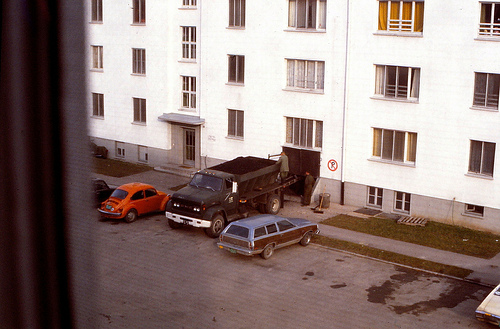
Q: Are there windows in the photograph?
A: Yes, there is a window.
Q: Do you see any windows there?
A: Yes, there is a window.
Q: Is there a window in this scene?
A: Yes, there is a window.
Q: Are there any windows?
A: Yes, there is a window.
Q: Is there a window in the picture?
A: Yes, there is a window.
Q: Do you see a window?
A: Yes, there is a window.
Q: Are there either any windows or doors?
A: Yes, there is a window.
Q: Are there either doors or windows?
A: Yes, there is a window.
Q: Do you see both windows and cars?
A: Yes, there are both a window and a car.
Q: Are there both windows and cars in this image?
A: Yes, there are both a window and a car.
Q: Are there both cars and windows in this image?
A: Yes, there are both a window and a car.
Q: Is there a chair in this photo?
A: No, there are no chairs.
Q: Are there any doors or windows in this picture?
A: Yes, there is a window.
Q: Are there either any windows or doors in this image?
A: Yes, there is a window.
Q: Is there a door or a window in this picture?
A: Yes, there is a window.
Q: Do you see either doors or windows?
A: Yes, there is a window.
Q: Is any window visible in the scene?
A: Yes, there is a window.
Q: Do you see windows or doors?
A: Yes, there is a window.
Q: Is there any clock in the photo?
A: No, there are no clocks.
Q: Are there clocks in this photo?
A: No, there are no clocks.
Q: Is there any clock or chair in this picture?
A: No, there are no clocks or chairs.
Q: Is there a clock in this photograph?
A: No, there are no clocks.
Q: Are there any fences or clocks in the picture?
A: No, there are no clocks or fences.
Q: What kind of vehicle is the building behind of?
A: The building is behind the car.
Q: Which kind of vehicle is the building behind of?
A: The building is behind the car.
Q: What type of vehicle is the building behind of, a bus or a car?
A: The building is behind a car.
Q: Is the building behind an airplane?
A: No, the building is behind the car.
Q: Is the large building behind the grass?
A: Yes, the building is behind the grass.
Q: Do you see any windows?
A: Yes, there is a window.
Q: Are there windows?
A: Yes, there is a window.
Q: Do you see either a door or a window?
A: Yes, there is a window.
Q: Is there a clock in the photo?
A: No, there are no clocks.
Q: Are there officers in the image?
A: No, there are no officers.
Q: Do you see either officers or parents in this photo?
A: No, there are no officers or parents.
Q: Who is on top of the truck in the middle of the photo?
A: The man is on top of the truck.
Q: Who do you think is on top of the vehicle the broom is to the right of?
A: The man is on top of the truck.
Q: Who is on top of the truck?
A: The man is on top of the truck.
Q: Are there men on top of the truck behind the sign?
A: Yes, there is a man on top of the truck.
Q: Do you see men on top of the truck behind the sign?
A: Yes, there is a man on top of the truck.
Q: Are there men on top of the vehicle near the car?
A: Yes, there is a man on top of the truck.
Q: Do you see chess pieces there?
A: No, there are no chess pieces.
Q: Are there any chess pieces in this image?
A: No, there are no chess pieces.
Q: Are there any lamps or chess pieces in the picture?
A: No, there are no chess pieces or lamps.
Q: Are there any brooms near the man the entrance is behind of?
A: Yes, there is a broom near the man.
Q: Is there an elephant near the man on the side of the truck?
A: No, there is a broom near the man.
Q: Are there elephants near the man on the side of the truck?
A: No, there is a broom near the man.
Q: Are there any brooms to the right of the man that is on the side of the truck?
A: Yes, there is a broom to the right of the man.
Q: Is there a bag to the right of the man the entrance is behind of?
A: No, there is a broom to the right of the man.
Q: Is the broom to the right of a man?
A: Yes, the broom is to the right of a man.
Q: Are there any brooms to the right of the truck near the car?
A: Yes, there is a broom to the right of the truck.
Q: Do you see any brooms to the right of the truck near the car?
A: Yes, there is a broom to the right of the truck.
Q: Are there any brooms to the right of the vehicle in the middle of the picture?
A: Yes, there is a broom to the right of the truck.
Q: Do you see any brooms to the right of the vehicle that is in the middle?
A: Yes, there is a broom to the right of the truck.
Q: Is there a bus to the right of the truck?
A: No, there is a broom to the right of the truck.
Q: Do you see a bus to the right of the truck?
A: No, there is a broom to the right of the truck.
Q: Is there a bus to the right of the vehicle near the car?
A: No, there is a broom to the right of the truck.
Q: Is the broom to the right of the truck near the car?
A: Yes, the broom is to the right of the truck.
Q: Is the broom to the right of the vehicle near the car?
A: Yes, the broom is to the right of the truck.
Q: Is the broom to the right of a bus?
A: No, the broom is to the right of the truck.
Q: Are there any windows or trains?
A: Yes, there is a window.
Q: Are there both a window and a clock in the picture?
A: No, there is a window but no clocks.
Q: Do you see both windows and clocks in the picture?
A: No, there is a window but no clocks.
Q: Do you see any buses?
A: No, there are no buses.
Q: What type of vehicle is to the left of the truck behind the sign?
A: The vehicle is a car.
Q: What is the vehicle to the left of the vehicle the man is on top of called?
A: The vehicle is a car.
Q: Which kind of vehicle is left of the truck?
A: The vehicle is a car.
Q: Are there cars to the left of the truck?
A: Yes, there is a car to the left of the truck.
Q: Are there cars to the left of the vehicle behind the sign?
A: Yes, there is a car to the left of the truck.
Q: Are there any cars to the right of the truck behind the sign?
A: No, the car is to the left of the truck.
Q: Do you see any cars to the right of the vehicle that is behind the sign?
A: No, the car is to the left of the truck.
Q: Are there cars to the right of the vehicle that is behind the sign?
A: No, the car is to the left of the truck.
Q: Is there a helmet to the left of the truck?
A: No, there is a car to the left of the truck.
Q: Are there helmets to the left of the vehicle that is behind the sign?
A: No, there is a car to the left of the truck.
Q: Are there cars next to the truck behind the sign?
A: Yes, there is a car next to the truck.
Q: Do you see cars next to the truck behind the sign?
A: Yes, there is a car next to the truck.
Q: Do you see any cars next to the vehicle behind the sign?
A: Yes, there is a car next to the truck.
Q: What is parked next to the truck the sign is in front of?
A: The car is parked next to the truck.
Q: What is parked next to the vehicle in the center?
A: The car is parked next to the truck.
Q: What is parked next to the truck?
A: The car is parked next to the truck.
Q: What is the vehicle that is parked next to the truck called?
A: The vehicle is a car.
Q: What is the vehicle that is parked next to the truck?
A: The vehicle is a car.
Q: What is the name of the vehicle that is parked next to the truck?
A: The vehicle is a car.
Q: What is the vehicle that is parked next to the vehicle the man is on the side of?
A: The vehicle is a car.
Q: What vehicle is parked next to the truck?
A: The vehicle is a car.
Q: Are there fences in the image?
A: No, there are no fences.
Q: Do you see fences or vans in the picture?
A: No, there are no fences or vans.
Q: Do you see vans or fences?
A: No, there are no fences or vans.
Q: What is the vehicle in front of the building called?
A: The vehicle is a car.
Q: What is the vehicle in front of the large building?
A: The vehicle is a car.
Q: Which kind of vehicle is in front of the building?
A: The vehicle is a car.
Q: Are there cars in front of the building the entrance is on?
A: Yes, there is a car in front of the building.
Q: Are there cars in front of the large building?
A: Yes, there is a car in front of the building.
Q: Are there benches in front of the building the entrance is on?
A: No, there is a car in front of the building.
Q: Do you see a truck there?
A: Yes, there is a truck.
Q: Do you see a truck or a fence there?
A: Yes, there is a truck.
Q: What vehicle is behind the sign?
A: The vehicle is a truck.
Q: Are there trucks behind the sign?
A: Yes, there is a truck behind the sign.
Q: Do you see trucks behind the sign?
A: Yes, there is a truck behind the sign.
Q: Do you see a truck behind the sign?
A: Yes, there is a truck behind the sign.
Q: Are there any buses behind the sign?
A: No, there is a truck behind the sign.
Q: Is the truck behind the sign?
A: Yes, the truck is behind the sign.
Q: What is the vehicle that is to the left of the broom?
A: The vehicle is a truck.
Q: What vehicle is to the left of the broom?
A: The vehicle is a truck.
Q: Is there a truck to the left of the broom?
A: Yes, there is a truck to the left of the broom.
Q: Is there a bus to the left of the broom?
A: No, there is a truck to the left of the broom.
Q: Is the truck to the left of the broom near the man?
A: Yes, the truck is to the left of the broom.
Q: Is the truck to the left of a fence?
A: No, the truck is to the left of the broom.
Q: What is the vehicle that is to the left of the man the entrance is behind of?
A: The vehicle is a truck.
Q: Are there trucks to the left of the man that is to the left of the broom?
A: Yes, there is a truck to the left of the man.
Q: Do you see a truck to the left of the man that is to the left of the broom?
A: Yes, there is a truck to the left of the man.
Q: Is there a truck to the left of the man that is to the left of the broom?
A: Yes, there is a truck to the left of the man.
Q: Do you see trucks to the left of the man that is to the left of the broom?
A: Yes, there is a truck to the left of the man.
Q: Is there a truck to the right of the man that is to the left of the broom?
A: No, the truck is to the left of the man.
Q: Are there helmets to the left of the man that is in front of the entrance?
A: No, there is a truck to the left of the man.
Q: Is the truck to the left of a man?
A: Yes, the truck is to the left of a man.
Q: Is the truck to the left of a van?
A: No, the truck is to the left of a man.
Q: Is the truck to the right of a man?
A: No, the truck is to the left of a man.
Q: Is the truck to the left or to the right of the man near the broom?
A: The truck is to the left of the man.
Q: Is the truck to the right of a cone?
A: No, the truck is to the right of the car.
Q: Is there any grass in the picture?
A: Yes, there is grass.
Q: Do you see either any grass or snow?
A: Yes, there is grass.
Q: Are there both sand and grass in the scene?
A: No, there is grass but no sand.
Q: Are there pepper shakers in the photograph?
A: No, there are no pepper shakers.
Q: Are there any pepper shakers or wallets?
A: No, there are no pepper shakers or wallets.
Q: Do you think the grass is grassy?
A: Yes, the grass is grassy.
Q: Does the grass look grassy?
A: Yes, the grass is grassy.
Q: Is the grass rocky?
A: No, the grass is grassy.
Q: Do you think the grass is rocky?
A: No, the grass is grassy.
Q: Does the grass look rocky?
A: No, the grass is grassy.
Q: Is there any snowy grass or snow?
A: No, there is grass but it is grassy.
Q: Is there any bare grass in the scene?
A: No, there is grass but it is grassy.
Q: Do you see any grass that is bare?
A: No, there is grass but it is grassy.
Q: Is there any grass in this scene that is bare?
A: No, there is grass but it is grassy.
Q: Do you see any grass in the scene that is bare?
A: No, there is grass but it is grassy.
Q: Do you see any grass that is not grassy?
A: No, there is grass but it is grassy.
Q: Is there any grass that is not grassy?
A: No, there is grass but it is grassy.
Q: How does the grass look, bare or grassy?
A: The grass is grassy.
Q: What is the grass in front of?
A: The grass is in front of the building.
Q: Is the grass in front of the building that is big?
A: Yes, the grass is in front of the building.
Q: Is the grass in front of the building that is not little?
A: Yes, the grass is in front of the building.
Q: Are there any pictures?
A: No, there are no pictures.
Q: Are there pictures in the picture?
A: No, there are no pictures.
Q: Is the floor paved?
A: Yes, the floor is paved.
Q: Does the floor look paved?
A: Yes, the floor is paved.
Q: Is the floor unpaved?
A: No, the floor is paved.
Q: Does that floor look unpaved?
A: No, the floor is paved.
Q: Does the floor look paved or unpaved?
A: The floor is paved.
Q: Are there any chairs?
A: No, there are no chairs.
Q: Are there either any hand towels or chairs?
A: No, there are no chairs or hand towels.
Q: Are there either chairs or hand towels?
A: No, there are no chairs or hand towels.